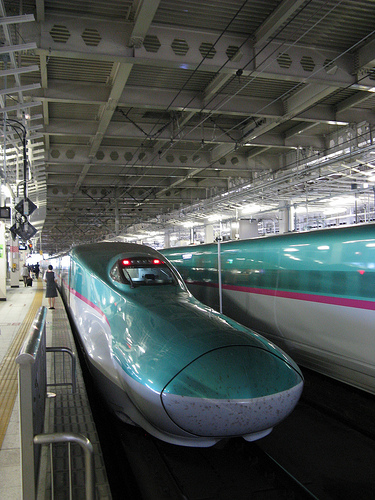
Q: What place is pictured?
A: It is a train station.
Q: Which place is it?
A: It is a train station.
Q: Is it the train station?
A: Yes, it is the train station.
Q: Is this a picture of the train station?
A: Yes, it is showing the train station.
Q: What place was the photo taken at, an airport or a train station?
A: It was taken at a train station.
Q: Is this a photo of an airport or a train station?
A: It is showing a train station.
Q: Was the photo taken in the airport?
A: No, the picture was taken in the train station.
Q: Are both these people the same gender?
A: Yes, all the people are female.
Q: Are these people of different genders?
A: No, all the people are female.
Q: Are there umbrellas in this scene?
A: No, there are no umbrellas.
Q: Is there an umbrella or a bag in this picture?
A: No, there are no umbrellas or bags.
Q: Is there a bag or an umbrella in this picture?
A: No, there are no umbrellas or bags.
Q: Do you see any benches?
A: No, there are no benches.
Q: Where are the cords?
A: The cords are at the train station.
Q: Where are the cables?
A: The cords are at the train station.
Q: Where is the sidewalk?
A: The sidewalk is at the train station.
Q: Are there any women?
A: Yes, there is a woman.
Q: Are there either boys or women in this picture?
A: Yes, there is a woman.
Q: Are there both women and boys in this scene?
A: No, there is a woman but no boys.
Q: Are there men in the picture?
A: No, there are no men.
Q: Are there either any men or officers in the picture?
A: No, there are no men or officers.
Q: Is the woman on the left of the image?
A: Yes, the woman is on the left of the image.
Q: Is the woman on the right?
A: No, the woman is on the left of the image.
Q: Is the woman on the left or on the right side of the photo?
A: The woman is on the left of the image.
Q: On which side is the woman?
A: The woman is on the left of the image.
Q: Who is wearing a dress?
A: The woman is wearing a dress.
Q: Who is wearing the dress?
A: The woman is wearing a dress.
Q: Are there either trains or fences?
A: Yes, there is a train.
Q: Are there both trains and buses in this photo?
A: No, there is a train but no buses.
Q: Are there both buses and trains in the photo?
A: No, there is a train but no buses.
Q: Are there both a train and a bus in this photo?
A: No, there is a train but no buses.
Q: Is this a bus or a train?
A: This is a train.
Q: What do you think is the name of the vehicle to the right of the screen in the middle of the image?
A: The vehicle is a train.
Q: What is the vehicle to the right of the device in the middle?
A: The vehicle is a train.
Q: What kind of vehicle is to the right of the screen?
A: The vehicle is a train.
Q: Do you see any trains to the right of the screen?
A: Yes, there is a train to the right of the screen.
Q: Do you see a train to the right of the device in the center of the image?
A: Yes, there is a train to the right of the screen.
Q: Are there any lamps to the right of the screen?
A: No, there is a train to the right of the screen.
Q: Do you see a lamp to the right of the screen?
A: No, there is a train to the right of the screen.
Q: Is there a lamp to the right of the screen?
A: No, there is a train to the right of the screen.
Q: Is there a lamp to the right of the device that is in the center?
A: No, there is a train to the right of the screen.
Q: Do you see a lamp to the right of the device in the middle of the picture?
A: No, there is a train to the right of the screen.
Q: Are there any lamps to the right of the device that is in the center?
A: No, there is a train to the right of the screen.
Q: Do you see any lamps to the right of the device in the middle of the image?
A: No, there is a train to the right of the screen.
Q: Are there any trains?
A: Yes, there is a train.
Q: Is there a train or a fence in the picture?
A: Yes, there is a train.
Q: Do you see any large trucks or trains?
A: Yes, there is a large train.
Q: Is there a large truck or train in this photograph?
A: Yes, there is a large train.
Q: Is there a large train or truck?
A: Yes, there is a large train.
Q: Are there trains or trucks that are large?
A: Yes, the train is large.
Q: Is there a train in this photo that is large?
A: Yes, there is a large train.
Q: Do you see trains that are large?
A: Yes, there is a train that is large.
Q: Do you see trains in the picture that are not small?
A: Yes, there is a large train.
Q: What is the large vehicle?
A: The vehicle is a train.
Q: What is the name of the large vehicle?
A: The vehicle is a train.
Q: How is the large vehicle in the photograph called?
A: The vehicle is a train.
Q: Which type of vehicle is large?
A: The vehicle is a train.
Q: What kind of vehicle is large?
A: The vehicle is a train.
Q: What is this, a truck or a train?
A: This is a train.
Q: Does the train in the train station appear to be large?
A: Yes, the train is large.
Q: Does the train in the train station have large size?
A: Yes, the train is large.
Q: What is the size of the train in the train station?
A: The train is large.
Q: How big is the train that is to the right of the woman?
A: The train is large.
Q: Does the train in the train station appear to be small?
A: No, the train is large.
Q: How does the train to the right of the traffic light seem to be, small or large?
A: The train is large.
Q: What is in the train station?
A: The train is in the train station.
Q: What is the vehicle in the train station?
A: The vehicle is a train.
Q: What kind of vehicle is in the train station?
A: The vehicle is a train.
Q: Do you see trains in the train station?
A: Yes, there is a train in the train station.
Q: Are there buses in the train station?
A: No, there is a train in the train station.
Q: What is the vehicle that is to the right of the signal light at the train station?
A: The vehicle is a train.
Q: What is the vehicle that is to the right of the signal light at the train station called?
A: The vehicle is a train.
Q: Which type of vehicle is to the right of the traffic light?
A: The vehicle is a train.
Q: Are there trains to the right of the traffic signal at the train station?
A: Yes, there is a train to the right of the traffic light.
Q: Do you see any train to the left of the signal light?
A: No, the train is to the right of the signal light.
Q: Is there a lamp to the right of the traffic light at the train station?
A: No, there is a train to the right of the traffic signal.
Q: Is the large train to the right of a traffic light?
A: Yes, the train is to the right of a traffic light.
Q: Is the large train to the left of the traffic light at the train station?
A: No, the train is to the right of the traffic light.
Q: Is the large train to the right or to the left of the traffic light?
A: The train is to the right of the traffic light.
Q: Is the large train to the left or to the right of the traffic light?
A: The train is to the right of the traffic light.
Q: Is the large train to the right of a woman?
A: Yes, the train is to the right of a woman.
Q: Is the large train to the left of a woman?
A: No, the train is to the right of a woman.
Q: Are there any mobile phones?
A: No, there are no mobile phones.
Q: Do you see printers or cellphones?
A: No, there are no cellphones or printers.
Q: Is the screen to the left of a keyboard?
A: No, the screen is to the left of the train.